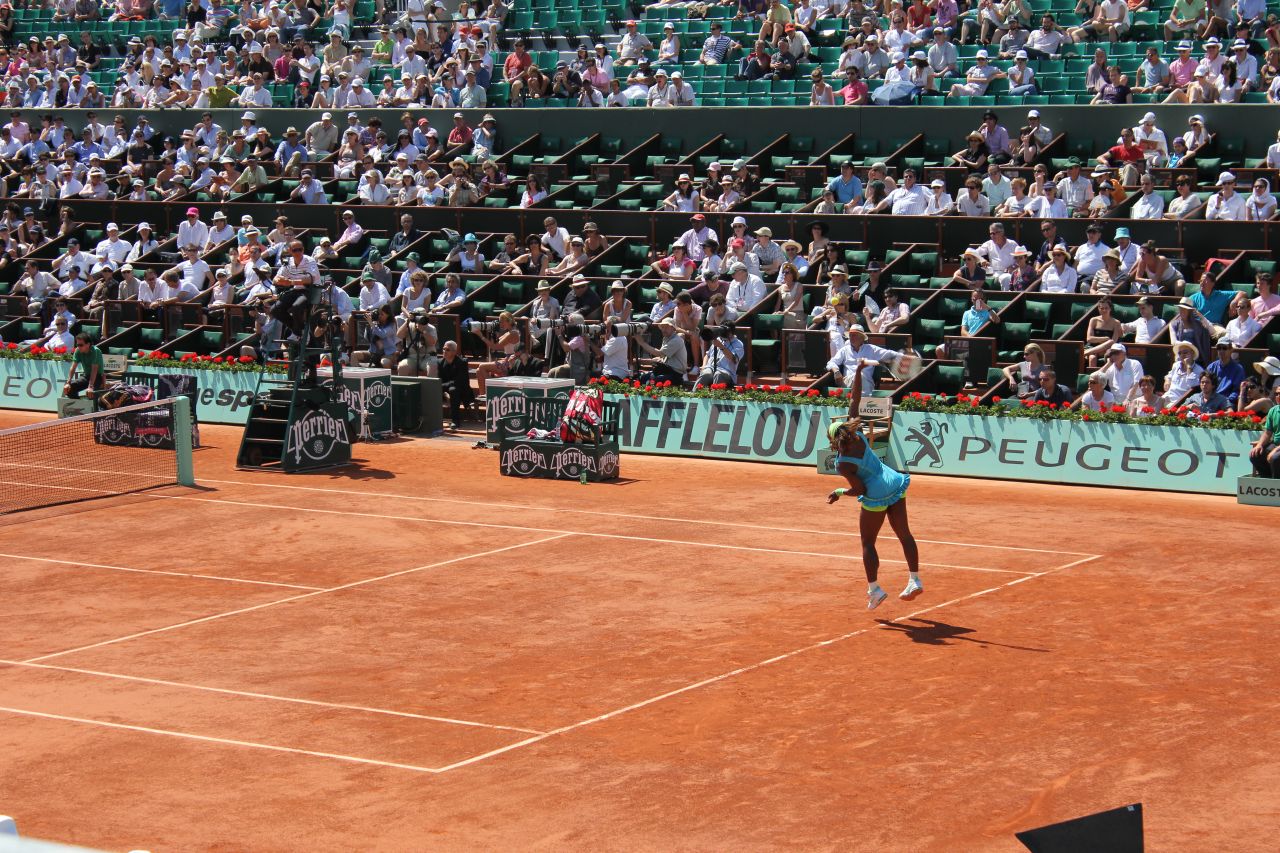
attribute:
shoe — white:
[899, 565, 933, 619]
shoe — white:
[861, 569, 899, 620]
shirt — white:
[727, 282, 761, 320]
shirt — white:
[1098, 366, 1145, 404]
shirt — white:
[338, 183, 396, 208]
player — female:
[811, 397, 926, 601]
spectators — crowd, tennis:
[7, 10, 1279, 414]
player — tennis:
[824, 348, 924, 604]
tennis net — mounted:
[8, 379, 210, 534]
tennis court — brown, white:
[5, 384, 1279, 848]